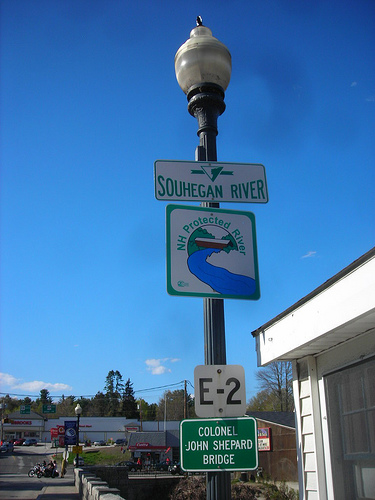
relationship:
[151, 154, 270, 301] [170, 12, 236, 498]
signs on light post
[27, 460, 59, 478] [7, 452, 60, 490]
motorcyclists driving on road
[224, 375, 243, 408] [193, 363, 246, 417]
number on a street sign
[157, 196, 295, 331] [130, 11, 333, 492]
sign on pole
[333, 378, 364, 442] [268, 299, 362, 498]
window in building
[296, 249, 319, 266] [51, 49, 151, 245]
white cloud in sky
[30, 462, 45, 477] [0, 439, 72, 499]
motorcycle cross road